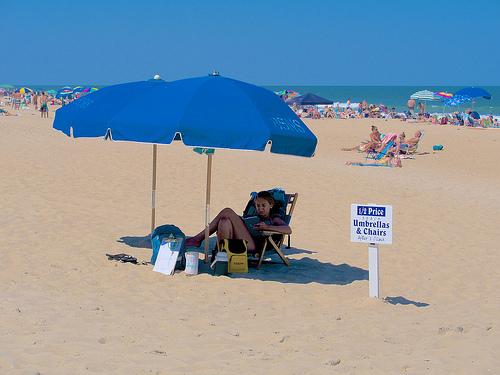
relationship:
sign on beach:
[351, 203, 392, 244] [2, 97, 498, 375]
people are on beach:
[3, 91, 499, 165] [2, 97, 498, 375]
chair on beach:
[242, 192, 298, 269] [2, 97, 498, 375]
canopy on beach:
[106, 74, 316, 157] [2, 97, 498, 375]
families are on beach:
[1, 88, 498, 128] [2, 97, 498, 375]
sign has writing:
[351, 203, 392, 244] [353, 207, 388, 238]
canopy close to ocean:
[106, 74, 316, 157] [24, 86, 499, 115]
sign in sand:
[351, 203, 392, 244] [3, 98, 499, 375]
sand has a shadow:
[3, 98, 499, 375] [220, 257, 369, 285]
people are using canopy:
[3, 91, 499, 165] [106, 74, 316, 157]